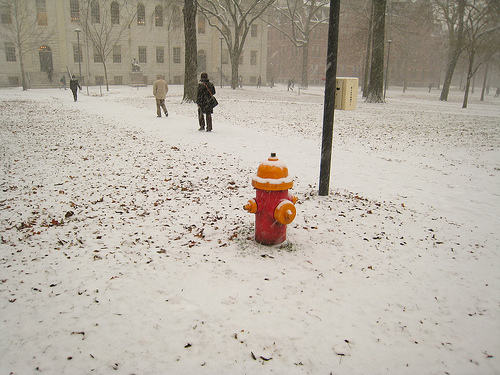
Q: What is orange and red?
A: Fire hydrant.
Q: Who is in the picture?
A: People.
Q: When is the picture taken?
A: Winter.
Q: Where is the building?
A: Background.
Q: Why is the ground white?
A: Snow.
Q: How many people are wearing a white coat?
A: One.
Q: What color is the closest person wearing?
A: Black.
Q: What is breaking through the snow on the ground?
A: Leaves.